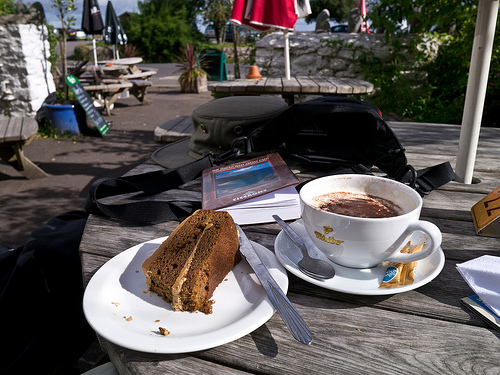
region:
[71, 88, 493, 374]
a round outdoor table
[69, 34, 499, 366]
several round wood outdoor tables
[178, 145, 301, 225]
a book book is on the table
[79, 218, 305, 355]
a slice of chocolate cake is on a white plate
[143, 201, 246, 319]
a slice of cake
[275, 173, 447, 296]
a cup with a thick liquid in it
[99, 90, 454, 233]
a black backpack is on the table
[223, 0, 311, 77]
a red closed umbrella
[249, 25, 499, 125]
a stone wall next to the seating area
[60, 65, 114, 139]
a sign leaning against a potted plant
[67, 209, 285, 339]
plate on the table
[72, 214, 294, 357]
the plate is white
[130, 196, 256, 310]
a piece of cake on the plate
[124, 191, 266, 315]
the cake is brown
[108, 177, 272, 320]
the cake is chocolate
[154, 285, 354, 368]
the table is grey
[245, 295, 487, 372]
the table is made of wood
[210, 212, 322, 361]
the knife is on the side of plate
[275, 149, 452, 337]
a cup and saucer on the table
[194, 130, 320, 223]
a book on the table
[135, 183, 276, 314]
chocolate cake on a saucer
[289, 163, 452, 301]
cup with coffee on a saucer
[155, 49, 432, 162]
black bag on a wooden table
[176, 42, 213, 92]
plants on a patio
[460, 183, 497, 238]
number 77 on a wooden table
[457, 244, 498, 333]
white napkin on a wooden table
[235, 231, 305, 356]
knife on a wooden table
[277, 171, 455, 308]
cup and saucer on a wooden table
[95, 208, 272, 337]
a piece of cake on a plate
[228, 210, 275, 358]
a grey metal knife on a plate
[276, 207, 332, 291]
a grey metal spoon on a saucer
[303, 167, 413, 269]
a tea cup filled with chocolate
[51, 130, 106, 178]
black concrete of the walkway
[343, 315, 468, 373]
grey wood surface of the table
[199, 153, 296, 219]
a hard cover book on the table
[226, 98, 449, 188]
a black fanny pack on the table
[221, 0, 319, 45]
a red and white umbrella in the table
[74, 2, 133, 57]
two black umbrellas in the distance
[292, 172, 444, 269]
the cup is white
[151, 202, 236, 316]
the cake is choclate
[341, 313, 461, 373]
the table is made of wood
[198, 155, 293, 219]
book is on the table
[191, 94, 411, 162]
bag is on the table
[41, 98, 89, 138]
the bucket is blue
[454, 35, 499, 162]
the pole is white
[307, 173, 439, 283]
hot choclate is in the cup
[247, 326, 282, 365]
shadow of spoon is on the table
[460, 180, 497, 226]
number 22 is on the sign